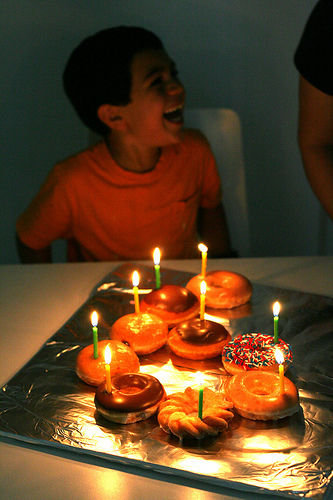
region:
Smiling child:
[57, 19, 204, 165]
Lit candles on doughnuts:
[60, 245, 330, 445]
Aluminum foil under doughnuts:
[233, 412, 331, 490]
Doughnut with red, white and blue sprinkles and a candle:
[223, 300, 297, 373]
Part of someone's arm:
[290, 69, 331, 215]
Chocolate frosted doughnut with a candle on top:
[92, 339, 163, 426]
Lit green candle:
[191, 367, 211, 417]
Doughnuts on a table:
[0, 245, 331, 499]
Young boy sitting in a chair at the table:
[8, 17, 262, 259]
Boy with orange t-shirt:
[15, 21, 243, 265]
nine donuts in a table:
[79, 258, 295, 440]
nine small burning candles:
[82, 237, 292, 424]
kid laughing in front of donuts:
[39, 36, 217, 248]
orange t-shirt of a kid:
[25, 150, 229, 245]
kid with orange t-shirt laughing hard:
[36, 32, 227, 247]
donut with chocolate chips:
[227, 331, 291, 373]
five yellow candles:
[110, 232, 286, 408]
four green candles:
[85, 248, 284, 412]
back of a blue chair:
[85, 100, 249, 238]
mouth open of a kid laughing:
[158, 104, 188, 125]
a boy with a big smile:
[16, 19, 245, 272]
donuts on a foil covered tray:
[13, 260, 323, 483]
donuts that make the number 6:
[30, 243, 326, 487]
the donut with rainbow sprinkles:
[219, 329, 295, 375]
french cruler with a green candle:
[155, 384, 227, 447]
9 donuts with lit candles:
[59, 236, 317, 474]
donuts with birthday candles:
[54, 237, 314, 462]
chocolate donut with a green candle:
[140, 274, 205, 325]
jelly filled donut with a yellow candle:
[105, 301, 166, 356]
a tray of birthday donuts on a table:
[4, 260, 322, 498]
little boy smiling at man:
[66, 50, 200, 161]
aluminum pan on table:
[30, 401, 90, 432]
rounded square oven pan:
[45, 291, 184, 473]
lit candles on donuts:
[110, 244, 259, 427]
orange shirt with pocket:
[71, 159, 213, 233]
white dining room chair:
[200, 94, 289, 211]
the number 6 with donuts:
[98, 253, 283, 425]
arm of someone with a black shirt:
[289, 73, 331, 204]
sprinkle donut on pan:
[214, 307, 274, 382]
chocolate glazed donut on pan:
[94, 375, 149, 423]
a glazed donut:
[195, 264, 252, 297]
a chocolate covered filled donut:
[143, 280, 194, 313]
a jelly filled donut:
[111, 311, 164, 350]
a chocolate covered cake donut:
[100, 369, 165, 420]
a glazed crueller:
[162, 385, 230, 436]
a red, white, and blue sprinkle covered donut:
[224, 328, 292, 367]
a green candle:
[152, 255, 166, 292]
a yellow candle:
[274, 359, 289, 392]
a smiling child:
[16, 48, 248, 257]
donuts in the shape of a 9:
[84, 256, 299, 442]